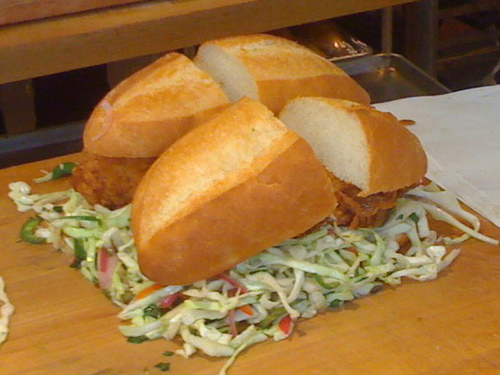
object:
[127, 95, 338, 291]
bread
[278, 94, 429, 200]
half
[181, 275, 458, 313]
vegetables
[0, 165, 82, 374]
board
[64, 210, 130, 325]
lettuce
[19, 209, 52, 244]
pepper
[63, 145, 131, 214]
meat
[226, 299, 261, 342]
carrot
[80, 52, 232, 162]
crust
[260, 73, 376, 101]
indent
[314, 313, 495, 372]
lines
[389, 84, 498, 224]
napkin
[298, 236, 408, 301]
cabbage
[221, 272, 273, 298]
onion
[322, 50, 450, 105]
tray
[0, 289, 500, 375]
table